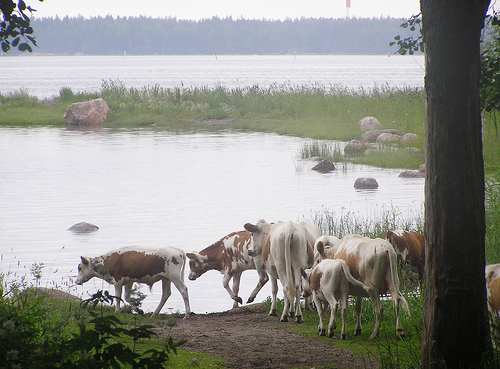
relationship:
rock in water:
[73, 212, 102, 242] [109, 203, 125, 224]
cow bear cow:
[301, 249, 366, 334] [64, 239, 195, 306]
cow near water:
[64, 239, 195, 306] [109, 203, 125, 224]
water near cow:
[109, 203, 125, 224] [64, 239, 195, 306]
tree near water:
[397, 22, 421, 58] [109, 203, 125, 224]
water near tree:
[109, 203, 125, 224] [397, 22, 421, 58]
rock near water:
[56, 99, 119, 126] [109, 203, 125, 224]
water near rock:
[165, 176, 213, 187] [73, 212, 102, 242]